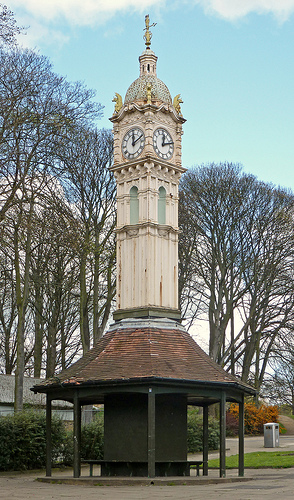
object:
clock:
[121, 128, 145, 160]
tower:
[108, 15, 187, 321]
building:
[30, 318, 257, 487]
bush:
[225, 402, 280, 437]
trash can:
[263, 421, 281, 448]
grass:
[191, 452, 293, 468]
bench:
[78, 458, 147, 476]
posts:
[46, 392, 52, 482]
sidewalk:
[1, 432, 294, 498]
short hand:
[131, 132, 135, 146]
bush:
[0, 409, 66, 471]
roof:
[30, 317, 259, 394]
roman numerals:
[124, 138, 128, 142]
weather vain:
[141, 14, 159, 50]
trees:
[0, 46, 47, 420]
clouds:
[0, 1, 292, 406]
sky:
[0, 2, 293, 408]